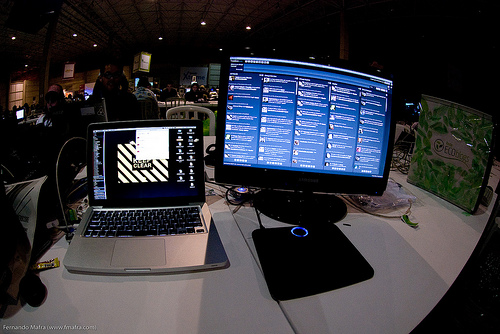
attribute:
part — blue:
[291, 224, 308, 236]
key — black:
[90, 221, 122, 231]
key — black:
[164, 212, 171, 222]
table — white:
[204, 123, 498, 332]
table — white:
[0, 159, 300, 332]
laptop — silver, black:
[70, 118, 235, 283]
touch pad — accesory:
[255, 225, 372, 308]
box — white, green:
[405, 95, 495, 220]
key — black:
[105, 209, 115, 218]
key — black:
[118, 207, 128, 216]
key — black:
[83, 225, 93, 238]